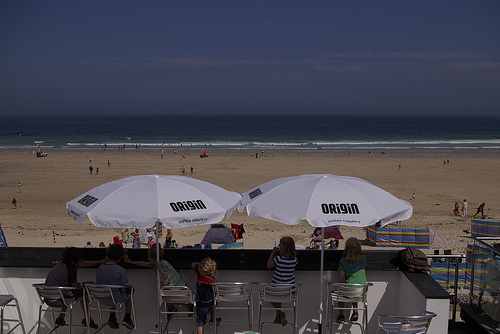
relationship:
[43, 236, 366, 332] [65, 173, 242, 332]
kids sitting under umbrella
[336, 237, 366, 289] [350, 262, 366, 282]
girl wearing shirt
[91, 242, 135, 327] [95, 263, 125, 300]
boy wearing shirt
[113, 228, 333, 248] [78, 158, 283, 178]
people on beach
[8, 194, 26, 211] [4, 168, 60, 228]
person standing in sand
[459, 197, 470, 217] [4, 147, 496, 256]
person standing in sand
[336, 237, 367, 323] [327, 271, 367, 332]
girl sitting in chair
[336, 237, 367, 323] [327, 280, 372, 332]
girl sitting in chair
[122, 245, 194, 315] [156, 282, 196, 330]
person sitting in chair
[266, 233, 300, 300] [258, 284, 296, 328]
person sitting in chair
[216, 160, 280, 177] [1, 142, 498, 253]
sand on beach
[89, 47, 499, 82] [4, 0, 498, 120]
clouds in sky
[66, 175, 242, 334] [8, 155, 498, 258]
umbrella over sand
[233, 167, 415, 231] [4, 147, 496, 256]
umbrella over sand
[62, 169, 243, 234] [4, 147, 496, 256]
umbrella over sand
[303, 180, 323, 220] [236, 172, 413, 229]
edge of an umbrella